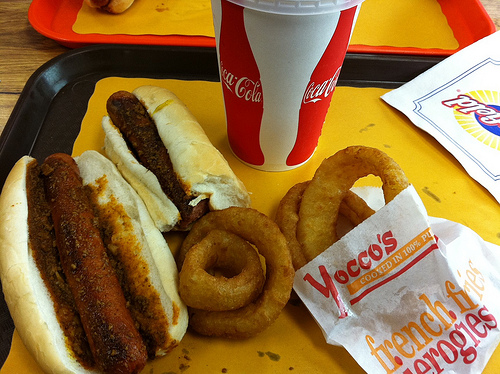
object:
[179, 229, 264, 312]
onion ring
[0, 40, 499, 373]
tray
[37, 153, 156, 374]
hotdog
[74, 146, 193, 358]
bun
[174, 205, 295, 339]
onion rings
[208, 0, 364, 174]
cup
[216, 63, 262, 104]
coca-cola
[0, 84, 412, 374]
food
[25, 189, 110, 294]
chili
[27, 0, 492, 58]
tray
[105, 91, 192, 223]
chili dog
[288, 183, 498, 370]
bag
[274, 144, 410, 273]
onion rings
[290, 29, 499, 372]
paper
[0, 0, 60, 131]
table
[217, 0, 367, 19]
lid